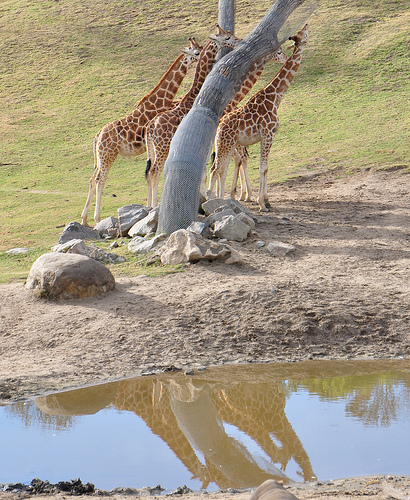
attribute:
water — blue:
[10, 430, 135, 491]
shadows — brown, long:
[32, 343, 321, 469]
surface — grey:
[90, 291, 210, 361]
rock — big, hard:
[19, 242, 117, 303]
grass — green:
[20, 159, 81, 254]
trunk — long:
[135, 53, 230, 221]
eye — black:
[171, 32, 202, 63]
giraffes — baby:
[56, 44, 330, 245]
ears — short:
[162, 30, 214, 61]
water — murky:
[122, 363, 320, 448]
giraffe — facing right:
[79, 35, 200, 227]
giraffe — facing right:
[141, 23, 243, 213]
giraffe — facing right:
[199, 46, 288, 201]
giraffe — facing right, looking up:
[205, 21, 310, 213]